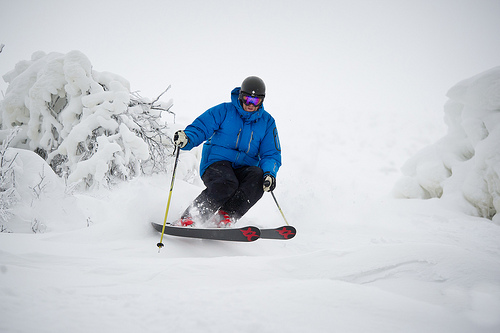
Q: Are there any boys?
A: No, there are no boys.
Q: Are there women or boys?
A: No, there are no boys or women.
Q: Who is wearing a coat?
A: The man is wearing a coat.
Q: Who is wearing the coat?
A: The man is wearing a coat.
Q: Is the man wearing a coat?
A: Yes, the man is wearing a coat.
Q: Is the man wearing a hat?
A: No, the man is wearing a coat.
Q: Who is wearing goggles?
A: The man is wearing goggles.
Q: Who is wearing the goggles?
A: The man is wearing goggles.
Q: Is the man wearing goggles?
A: Yes, the man is wearing goggles.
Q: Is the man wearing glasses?
A: No, the man is wearing goggles.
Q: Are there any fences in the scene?
A: No, there are no fences.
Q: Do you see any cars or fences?
A: No, there are no fences or cars.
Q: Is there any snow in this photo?
A: Yes, there is snow.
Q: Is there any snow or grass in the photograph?
A: Yes, there is snow.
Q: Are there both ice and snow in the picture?
A: No, there is snow but no ice.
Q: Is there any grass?
A: No, there is no grass.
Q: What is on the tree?
A: The snow is on the tree.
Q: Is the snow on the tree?
A: Yes, the snow is on the tree.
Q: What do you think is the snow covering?
A: The snow is covering the bush.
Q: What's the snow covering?
A: The snow is covering the bush.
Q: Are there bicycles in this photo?
A: No, there are no bicycles.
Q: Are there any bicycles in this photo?
A: No, there are no bicycles.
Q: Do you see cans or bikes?
A: No, there are no bikes or cans.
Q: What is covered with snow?
A: The shrub is covered with snow.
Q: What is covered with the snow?
A: The shrub is covered with snow.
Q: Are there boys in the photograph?
A: No, there are no boys.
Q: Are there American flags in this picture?
A: No, there are no American flags.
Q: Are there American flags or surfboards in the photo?
A: No, there are no American flags or surfboards.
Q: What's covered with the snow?
A: The bush is covered with snow.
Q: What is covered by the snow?
A: The bush is covered by the snow.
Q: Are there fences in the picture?
A: No, there are no fences.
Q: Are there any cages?
A: No, there are no cages.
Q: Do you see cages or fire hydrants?
A: No, there are no cages or fire hydrants.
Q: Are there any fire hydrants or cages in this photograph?
A: No, there are no cages or fire hydrants.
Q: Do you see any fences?
A: No, there are no fences.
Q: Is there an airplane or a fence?
A: No, there are no fences or airplanes.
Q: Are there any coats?
A: Yes, there is a coat.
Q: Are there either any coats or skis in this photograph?
A: Yes, there is a coat.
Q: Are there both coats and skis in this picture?
A: Yes, there are both a coat and skis.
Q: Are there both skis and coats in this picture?
A: Yes, there are both a coat and skis.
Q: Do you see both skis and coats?
A: Yes, there are both a coat and skis.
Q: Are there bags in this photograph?
A: No, there are no bags.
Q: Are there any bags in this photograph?
A: No, there are no bags.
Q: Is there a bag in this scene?
A: No, there are no bags.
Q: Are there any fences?
A: No, there are no fences.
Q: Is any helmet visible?
A: Yes, there is a helmet.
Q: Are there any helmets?
A: Yes, there is a helmet.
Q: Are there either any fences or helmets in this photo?
A: Yes, there is a helmet.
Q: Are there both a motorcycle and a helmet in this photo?
A: No, there is a helmet but no motorcycles.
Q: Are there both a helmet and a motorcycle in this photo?
A: No, there is a helmet but no motorcycles.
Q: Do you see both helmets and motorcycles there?
A: No, there is a helmet but no motorcycles.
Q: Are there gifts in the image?
A: No, there are no gifts.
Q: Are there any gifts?
A: No, there are no gifts.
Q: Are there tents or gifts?
A: No, there are no gifts or tents.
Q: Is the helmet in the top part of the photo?
A: Yes, the helmet is in the top of the image.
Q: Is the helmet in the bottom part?
A: No, the helmet is in the top of the image.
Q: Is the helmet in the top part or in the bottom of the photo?
A: The helmet is in the top of the image.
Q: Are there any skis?
A: Yes, there are skis.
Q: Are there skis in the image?
A: Yes, there are skis.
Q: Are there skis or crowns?
A: Yes, there are skis.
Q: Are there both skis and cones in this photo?
A: No, there are skis but no cones.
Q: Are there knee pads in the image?
A: No, there are no knee pads.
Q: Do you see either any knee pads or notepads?
A: No, there are no knee pads or notepads.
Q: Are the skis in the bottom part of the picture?
A: Yes, the skis are in the bottom of the image.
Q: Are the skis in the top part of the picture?
A: No, the skis are in the bottom of the image.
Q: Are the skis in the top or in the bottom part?
A: The skis are in the bottom of the image.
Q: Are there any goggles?
A: Yes, there are goggles.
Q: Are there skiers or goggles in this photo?
A: Yes, there are goggles.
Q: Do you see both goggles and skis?
A: Yes, there are both goggles and skis.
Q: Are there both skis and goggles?
A: Yes, there are both goggles and skis.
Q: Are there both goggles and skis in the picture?
A: Yes, there are both goggles and skis.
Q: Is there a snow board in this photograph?
A: No, there are no snowboards.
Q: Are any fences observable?
A: No, there are no fences.